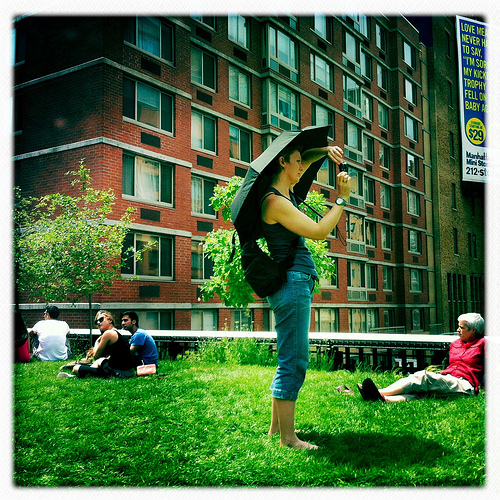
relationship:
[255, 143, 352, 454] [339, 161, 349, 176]
woman has cell phone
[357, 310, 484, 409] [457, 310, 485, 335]
man has hair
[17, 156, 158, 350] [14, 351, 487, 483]
trees are in grass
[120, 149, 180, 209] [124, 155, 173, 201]
window has curtains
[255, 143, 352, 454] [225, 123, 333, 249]
woman has umbrella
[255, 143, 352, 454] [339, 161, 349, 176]
woman holding cell phone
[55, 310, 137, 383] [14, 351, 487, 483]
people are sitting on grass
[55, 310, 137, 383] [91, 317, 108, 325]
people wearing sunglasses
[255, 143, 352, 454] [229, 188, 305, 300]
woman has purse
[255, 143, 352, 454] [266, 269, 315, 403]
woman wearing jeans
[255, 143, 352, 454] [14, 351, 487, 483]
woman standing on grass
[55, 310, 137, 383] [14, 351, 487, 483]
people sitting on grass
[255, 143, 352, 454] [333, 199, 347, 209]
woman has wristwatch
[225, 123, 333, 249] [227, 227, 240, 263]
umbrella has string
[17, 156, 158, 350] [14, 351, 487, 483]
trees growing in grass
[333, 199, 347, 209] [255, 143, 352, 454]
wristwatch on woman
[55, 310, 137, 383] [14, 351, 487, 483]
people sitting in grass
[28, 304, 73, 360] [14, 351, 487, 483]
man sitting in grass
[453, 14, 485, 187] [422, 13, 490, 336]
sign on building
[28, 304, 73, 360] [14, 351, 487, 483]
man sitting on grass